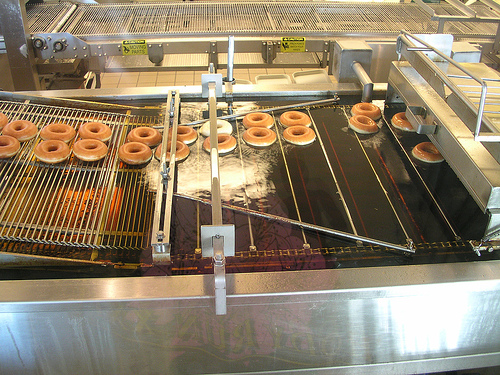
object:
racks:
[0, 0, 496, 38]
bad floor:
[90, 64, 207, 84]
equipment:
[25, 4, 466, 74]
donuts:
[169, 97, 455, 242]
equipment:
[6, 44, 490, 373]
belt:
[0, 85, 494, 297]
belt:
[0, 0, 497, 60]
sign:
[280, 35, 306, 54]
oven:
[27, 39, 407, 317]